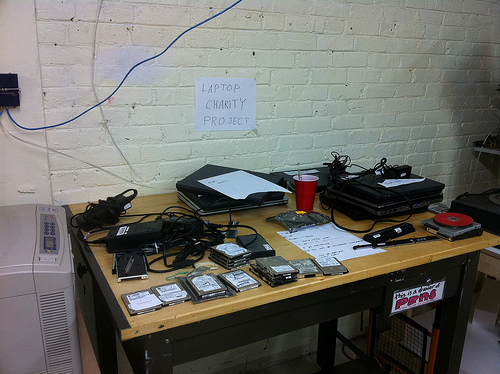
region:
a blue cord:
[18, 10, 268, 127]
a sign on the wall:
[195, 77, 253, 129]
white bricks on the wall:
[273, 10, 485, 126]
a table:
[79, 153, 479, 370]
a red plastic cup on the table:
[297, 173, 319, 210]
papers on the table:
[281, 218, 372, 257]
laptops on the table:
[334, 153, 438, 219]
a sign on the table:
[386, 280, 450, 310]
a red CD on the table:
[436, 206, 473, 228]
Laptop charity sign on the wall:
[192, 68, 264, 130]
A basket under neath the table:
[380, 316, 445, 371]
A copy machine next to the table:
[4, 205, 90, 367]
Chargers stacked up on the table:
[89, 192, 244, 269]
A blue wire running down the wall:
[13, 4, 256, 145]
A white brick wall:
[64, 16, 484, 338]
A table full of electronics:
[69, 210, 490, 371]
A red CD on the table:
[436, 214, 472, 229]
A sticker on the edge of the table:
[395, 277, 444, 314]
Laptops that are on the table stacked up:
[185, 158, 437, 238]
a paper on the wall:
[196, 82, 259, 134]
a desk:
[248, 214, 262, 229]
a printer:
[6, 202, 72, 282]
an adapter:
[3, 79, 23, 112]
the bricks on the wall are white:
[312, 49, 424, 147]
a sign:
[392, 290, 444, 310]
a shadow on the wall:
[458, 72, 483, 114]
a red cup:
[290, 173, 318, 207]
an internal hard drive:
[119, 288, 164, 315]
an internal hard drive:
[150, 280, 190, 310]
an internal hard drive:
[187, 272, 226, 298]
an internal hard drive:
[220, 268, 261, 293]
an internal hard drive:
[256, 253, 297, 279]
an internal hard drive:
[287, 255, 322, 278]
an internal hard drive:
[310, 254, 348, 276]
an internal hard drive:
[209, 243, 249, 258]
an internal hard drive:
[213, 250, 247, 263]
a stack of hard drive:
[206, 240, 251, 271]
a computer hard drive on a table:
[122, 282, 162, 315]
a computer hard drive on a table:
[148, 279, 196, 306]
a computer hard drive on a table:
[218, 268, 260, 295]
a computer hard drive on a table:
[308, 249, 349, 277]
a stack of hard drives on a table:
[207, 237, 253, 269]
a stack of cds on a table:
[432, 208, 477, 230]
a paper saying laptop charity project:
[190, 74, 262, 134]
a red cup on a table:
[289, 172, 321, 214]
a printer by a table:
[1, 202, 81, 373]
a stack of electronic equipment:
[317, 164, 451, 223]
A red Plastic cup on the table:
[290, 167, 320, 217]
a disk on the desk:
[129, 290, 154, 332]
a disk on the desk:
[166, 283, 191, 325]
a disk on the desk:
[174, 270, 216, 305]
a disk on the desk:
[313, 238, 347, 278]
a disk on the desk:
[215, 238, 240, 266]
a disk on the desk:
[433, 208, 476, 240]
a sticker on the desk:
[378, 259, 468, 334]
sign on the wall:
[196, 69, 262, 129]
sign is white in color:
[191, 72, 262, 129]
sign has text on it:
[192, 72, 262, 133]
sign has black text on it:
[193, 74, 263, 136]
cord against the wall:
[10, 10, 240, 136]